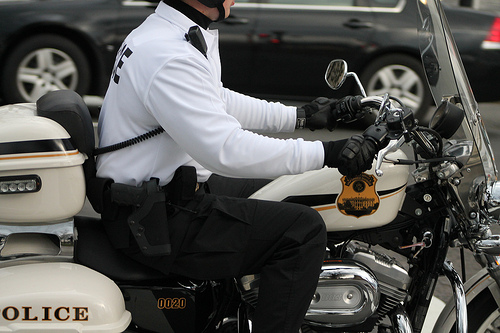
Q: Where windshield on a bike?
A: In front.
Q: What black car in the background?
A: Car with silver rims.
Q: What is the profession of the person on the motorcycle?
A: Police officer.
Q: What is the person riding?
A: Motorcycle.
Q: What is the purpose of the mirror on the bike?
A: To see behind.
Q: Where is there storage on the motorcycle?
A: Box on back.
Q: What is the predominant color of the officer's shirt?
A: White.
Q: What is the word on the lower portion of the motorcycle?
A: Police.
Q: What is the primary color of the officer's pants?
A: Black.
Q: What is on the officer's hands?
A: Gloves.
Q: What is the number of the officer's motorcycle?
A: 0020.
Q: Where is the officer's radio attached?
A: Front of shirt.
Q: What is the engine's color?
A: Silver.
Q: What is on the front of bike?
A: Windshield.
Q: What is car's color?
A: Black.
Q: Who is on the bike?
A: Police officer.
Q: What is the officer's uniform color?
A: White and black.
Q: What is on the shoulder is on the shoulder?
A: Handheld radio transmitter.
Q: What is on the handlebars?
A: Hands.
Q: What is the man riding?
A: A motorcycle.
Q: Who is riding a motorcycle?
A: A police officer.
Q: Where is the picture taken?
A: On a street.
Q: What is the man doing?
A: Riding a motorcycle.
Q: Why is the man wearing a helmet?
A: He's riding a motorcycle.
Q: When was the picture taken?
A: Daytime.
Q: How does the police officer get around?
A: He rides a motorcycle.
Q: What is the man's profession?
A: Police officer.